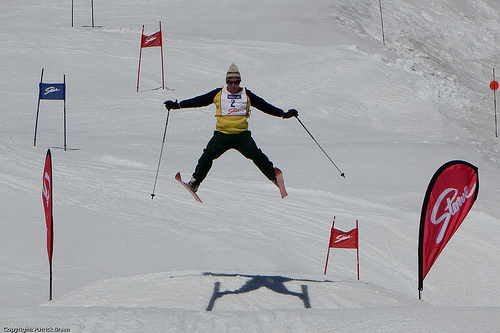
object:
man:
[161, 62, 298, 205]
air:
[0, 0, 497, 333]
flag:
[141, 31, 163, 48]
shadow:
[168, 271, 335, 311]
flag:
[39, 82, 67, 101]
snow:
[0, 3, 499, 332]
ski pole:
[293, 111, 346, 178]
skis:
[174, 171, 205, 203]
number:
[230, 99, 236, 107]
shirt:
[213, 86, 252, 135]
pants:
[191, 129, 277, 185]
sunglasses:
[225, 78, 241, 85]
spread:
[174, 148, 289, 204]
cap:
[225, 62, 241, 79]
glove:
[163, 100, 181, 110]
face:
[226, 80, 239, 93]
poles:
[150, 101, 174, 200]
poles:
[132, 23, 146, 93]